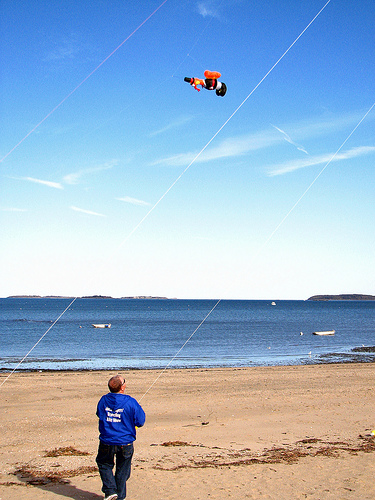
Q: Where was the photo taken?
A: Beach.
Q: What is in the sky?
A: Kite.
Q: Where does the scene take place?
A: On the beach.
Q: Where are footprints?
A: On the sand.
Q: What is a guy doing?
A: Flying a kite.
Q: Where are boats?
A: In the ocean.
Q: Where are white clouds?
A: In the sky.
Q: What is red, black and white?
A: Kite.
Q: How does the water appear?
A: Calm.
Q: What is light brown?
A: The sand.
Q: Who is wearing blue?
A: Man flying kite.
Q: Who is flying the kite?
A: Man in blue jacket.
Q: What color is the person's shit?
A: Blue.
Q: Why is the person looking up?
A: He's watching the kite.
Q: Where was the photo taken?
A: The beach.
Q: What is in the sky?
A: A kite.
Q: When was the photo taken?
A: During the day.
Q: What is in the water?
A: Boats.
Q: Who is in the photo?
A: A man.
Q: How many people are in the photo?
A: One.